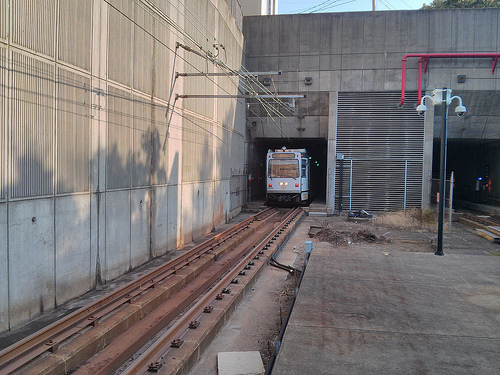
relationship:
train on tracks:
[209, 114, 371, 231] [3, 205, 309, 374]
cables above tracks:
[107, 0, 304, 125] [3, 205, 309, 374]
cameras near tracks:
[412, 82, 467, 120] [3, 205, 309, 374]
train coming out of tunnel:
[265, 146, 321, 206] [246, 127, 336, 213]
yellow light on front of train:
[279, 182, 283, 187] [266, 148, 313, 205]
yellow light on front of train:
[284, 182, 290, 189] [266, 148, 313, 205]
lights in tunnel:
[308, 155, 324, 172] [248, 138, 327, 213]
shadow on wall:
[188, 140, 225, 237] [1, 2, 256, 331]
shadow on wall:
[220, 64, 255, 216] [1, 2, 256, 331]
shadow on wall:
[0, 130, 182, 337] [1, 2, 256, 331]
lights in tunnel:
[476, 176, 496, 192] [432, 131, 495, 221]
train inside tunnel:
[265, 146, 321, 206] [248, 128, 331, 201]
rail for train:
[53, 212, 305, 373] [261, 141, 313, 208]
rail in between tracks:
[0, 206, 308, 374] [3, 205, 309, 374]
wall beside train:
[37, 32, 123, 186] [264, 147, 310, 207]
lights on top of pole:
[416, 88, 466, 117] [433, 101, 447, 254]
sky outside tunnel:
[276, 0, 426, 10] [251, 134, 329, 212]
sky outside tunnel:
[276, 0, 426, 10] [424, 133, 498, 215]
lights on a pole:
[416, 89, 474, 123] [435, 81, 450, 253]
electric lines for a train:
[134, 1, 296, 125] [262, 147, 313, 204]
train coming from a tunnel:
[265, 146, 321, 206] [259, 129, 331, 219]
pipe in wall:
[398, 52, 499, 108] [242, 2, 499, 208]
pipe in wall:
[394, 47, 494, 115] [242, 2, 499, 208]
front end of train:
[264, 147, 301, 204] [263, 142, 323, 210]